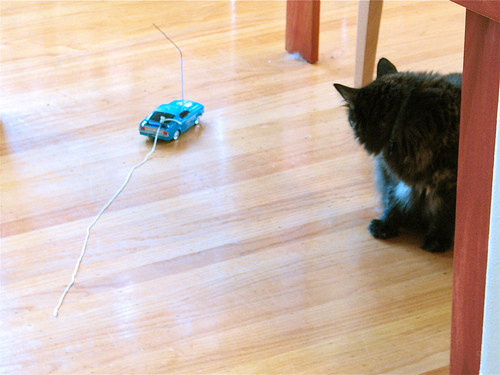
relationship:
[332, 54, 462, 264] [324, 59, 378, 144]
cat has ear